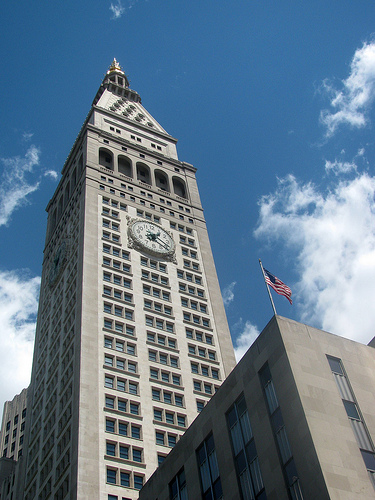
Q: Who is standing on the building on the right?
A: No one.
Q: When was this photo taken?
A: Daytime.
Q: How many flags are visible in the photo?
A: One.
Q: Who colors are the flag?
A: Red, white, blue.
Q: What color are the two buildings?
A: Grey.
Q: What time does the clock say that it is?
A: 1:20.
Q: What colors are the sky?
A: Blue, white.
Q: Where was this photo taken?
A: Outside a tall building.